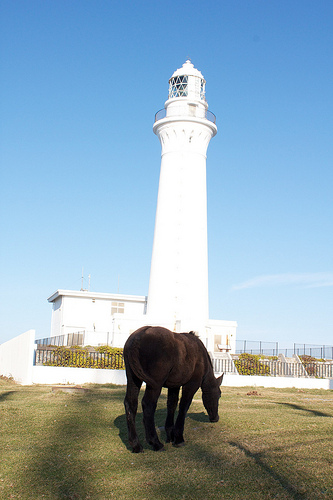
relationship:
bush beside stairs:
[234, 349, 271, 374] [212, 350, 228, 355]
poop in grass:
[236, 388, 262, 395] [1, 375, 332, 498]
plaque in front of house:
[217, 341, 230, 350] [47, 287, 236, 357]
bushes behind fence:
[41, 344, 317, 373] [34, 346, 331, 379]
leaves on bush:
[231, 352, 269, 377] [234, 352, 269, 375]